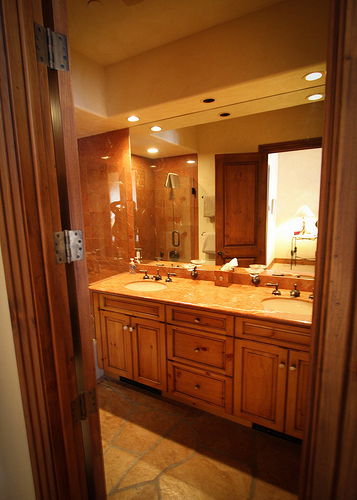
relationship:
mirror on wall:
[128, 83, 333, 274] [195, 100, 331, 286]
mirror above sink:
[128, 83, 333, 274] [88, 269, 322, 442]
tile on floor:
[93, 377, 325, 499] [57, 327, 356, 495]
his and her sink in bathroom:
[88, 269, 322, 442] [64, 2, 355, 494]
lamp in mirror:
[291, 205, 320, 253] [128, 83, 333, 274]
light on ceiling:
[302, 69, 326, 84] [107, 70, 329, 124]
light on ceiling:
[128, 113, 141, 123] [107, 70, 329, 124]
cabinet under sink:
[93, 289, 314, 443] [88, 269, 322, 442]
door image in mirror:
[216, 137, 326, 277] [128, 83, 333, 274]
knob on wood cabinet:
[125, 325, 128, 330] [88, 269, 322, 442]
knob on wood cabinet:
[130, 328, 132, 330] [88, 269, 322, 442]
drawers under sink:
[93, 289, 314, 443] [88, 269, 322, 442]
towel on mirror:
[164, 173, 178, 189] [128, 83, 333, 274]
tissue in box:
[221, 257, 237, 271] [216, 268, 234, 287]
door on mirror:
[216, 137, 326, 277] [128, 83, 333, 274]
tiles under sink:
[93, 377, 325, 499] [88, 269, 322, 442]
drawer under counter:
[93, 289, 168, 324] [87, 267, 332, 334]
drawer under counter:
[99, 312, 132, 381] [87, 267, 332, 334]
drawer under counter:
[130, 320, 168, 396] [87, 267, 332, 334]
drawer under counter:
[169, 303, 234, 338] [87, 267, 332, 334]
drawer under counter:
[237, 316, 323, 354] [87, 267, 332, 334]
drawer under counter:
[233, 339, 289, 432] [87, 267, 332, 334]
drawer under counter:
[165, 322, 236, 379] [87, 267, 332, 334]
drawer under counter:
[167, 359, 236, 411] [87, 267, 332, 334]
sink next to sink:
[125, 281, 165, 291] [261, 290, 320, 326]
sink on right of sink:
[261, 290, 320, 326] [125, 281, 165, 291]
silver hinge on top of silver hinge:
[32, 23, 70, 74] [53, 230, 83, 265]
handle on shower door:
[173, 230, 182, 248] [154, 172, 194, 264]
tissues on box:
[221, 257, 237, 271] [216, 268, 234, 287]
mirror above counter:
[128, 83, 333, 274] [87, 267, 332, 334]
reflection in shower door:
[113, 187, 149, 264] [154, 172, 194, 264]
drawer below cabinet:
[93, 289, 168, 324] [93, 289, 314, 443]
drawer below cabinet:
[99, 312, 132, 381] [93, 289, 314, 443]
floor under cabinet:
[57, 327, 356, 495] [93, 289, 314, 443]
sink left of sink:
[125, 281, 165, 291] [261, 290, 320, 326]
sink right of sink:
[261, 290, 320, 326] [125, 281, 165, 291]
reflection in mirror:
[113, 187, 149, 264] [128, 83, 333, 274]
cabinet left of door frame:
[93, 289, 314, 443] [298, 1, 355, 498]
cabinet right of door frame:
[93, 289, 314, 443] [1, 0, 109, 499]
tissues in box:
[221, 257, 237, 271] [216, 268, 234, 287]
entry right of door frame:
[64, 0, 331, 499] [1, 0, 109, 499]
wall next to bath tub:
[195, 100, 331, 286] [61, 128, 128, 382]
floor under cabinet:
[93, 377, 325, 499] [93, 289, 314, 443]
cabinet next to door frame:
[93, 289, 314, 443] [298, 1, 355, 498]